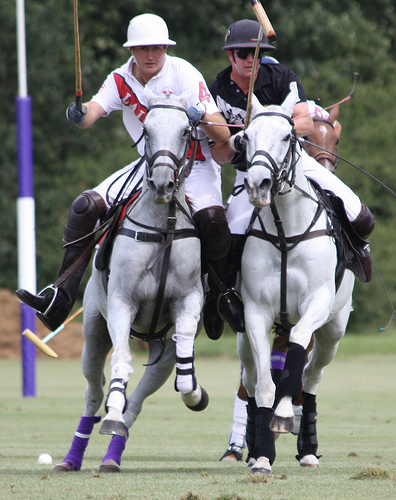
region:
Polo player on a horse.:
[17, 4, 228, 471]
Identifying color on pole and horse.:
[12, 288, 149, 465]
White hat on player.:
[123, 11, 177, 55]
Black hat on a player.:
[223, 16, 281, 56]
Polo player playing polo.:
[212, 15, 360, 476]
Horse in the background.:
[297, 94, 348, 175]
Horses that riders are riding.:
[55, 86, 374, 478]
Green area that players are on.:
[0, 328, 386, 498]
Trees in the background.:
[1, 1, 390, 334]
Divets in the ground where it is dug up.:
[4, 399, 391, 498]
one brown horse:
[280, 87, 376, 198]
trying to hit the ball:
[15, 307, 107, 497]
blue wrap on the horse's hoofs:
[71, 415, 169, 497]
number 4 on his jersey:
[187, 77, 212, 127]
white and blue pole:
[4, 97, 54, 391]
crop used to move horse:
[299, 129, 394, 200]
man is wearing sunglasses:
[232, 42, 293, 69]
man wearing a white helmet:
[96, 4, 178, 80]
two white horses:
[125, 81, 323, 347]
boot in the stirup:
[30, 259, 78, 342]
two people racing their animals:
[91, 21, 307, 159]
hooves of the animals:
[71, 335, 216, 473]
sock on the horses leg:
[51, 411, 97, 481]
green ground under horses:
[172, 451, 227, 491]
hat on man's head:
[120, 10, 182, 55]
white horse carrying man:
[143, 87, 189, 174]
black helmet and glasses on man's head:
[225, 14, 273, 72]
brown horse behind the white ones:
[313, 103, 359, 170]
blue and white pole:
[1, 220, 47, 388]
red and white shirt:
[117, 66, 194, 127]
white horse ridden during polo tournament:
[132, 89, 203, 432]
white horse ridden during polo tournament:
[241, 87, 310, 399]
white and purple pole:
[11, 13, 44, 277]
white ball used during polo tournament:
[30, 453, 56, 470]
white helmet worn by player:
[121, 14, 174, 49]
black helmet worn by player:
[218, 18, 274, 53]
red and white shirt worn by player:
[99, 65, 210, 96]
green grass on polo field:
[148, 409, 213, 488]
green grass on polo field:
[349, 346, 389, 445]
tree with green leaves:
[308, 12, 386, 90]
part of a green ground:
[176, 469, 200, 494]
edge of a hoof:
[99, 415, 135, 441]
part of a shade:
[177, 458, 196, 472]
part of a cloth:
[63, 422, 88, 471]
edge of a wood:
[40, 336, 60, 370]